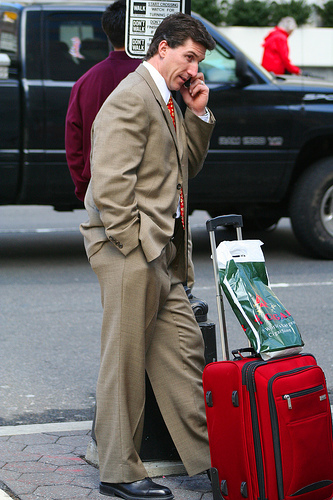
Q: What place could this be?
A: It is a street.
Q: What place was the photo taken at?
A: It was taken at the street.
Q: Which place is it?
A: It is a street.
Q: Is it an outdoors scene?
A: Yes, it is outdoors.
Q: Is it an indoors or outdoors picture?
A: It is outdoors.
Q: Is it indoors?
A: No, it is outdoors.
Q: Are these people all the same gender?
A: No, they are both male and female.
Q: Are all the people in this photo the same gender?
A: No, they are both male and female.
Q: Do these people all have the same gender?
A: No, they are both male and female.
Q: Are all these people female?
A: No, they are both male and female.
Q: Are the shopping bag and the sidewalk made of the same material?
A: No, the shopping bag is made of plastic and the sidewalk is made of cement.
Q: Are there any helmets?
A: No, there are no helmets.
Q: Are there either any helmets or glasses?
A: No, there are no helmets or glasses.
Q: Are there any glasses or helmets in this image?
A: No, there are no helmets or glasses.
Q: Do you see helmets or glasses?
A: No, there are no helmets or glasses.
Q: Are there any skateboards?
A: No, there are no skateboards.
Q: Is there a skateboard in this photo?
A: No, there are no skateboards.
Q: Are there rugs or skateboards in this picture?
A: No, there are no skateboards or rugs.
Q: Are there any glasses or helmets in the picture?
A: No, there are no glasses or helmets.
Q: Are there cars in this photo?
A: No, there are no cars.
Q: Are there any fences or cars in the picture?
A: No, there are no cars or fences.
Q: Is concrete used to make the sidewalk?
A: Yes, the sidewalk is made of concrete.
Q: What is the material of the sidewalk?
A: The sidewalk is made of cement.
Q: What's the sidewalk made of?
A: The sidewalk is made of concrete.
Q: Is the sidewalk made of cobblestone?
A: No, the sidewalk is made of concrete.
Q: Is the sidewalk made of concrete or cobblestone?
A: The sidewalk is made of concrete.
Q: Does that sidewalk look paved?
A: Yes, the sidewalk is paved.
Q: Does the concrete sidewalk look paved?
A: Yes, the sidewalk is paved.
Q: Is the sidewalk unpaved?
A: No, the sidewalk is paved.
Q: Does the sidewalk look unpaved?
A: No, the sidewalk is paved.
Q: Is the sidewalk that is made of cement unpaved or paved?
A: The sidewalk is paved.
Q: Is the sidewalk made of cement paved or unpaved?
A: The sidewalk is paved.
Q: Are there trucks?
A: Yes, there is a truck.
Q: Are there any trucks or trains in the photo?
A: Yes, there is a truck.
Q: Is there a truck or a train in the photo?
A: Yes, there is a truck.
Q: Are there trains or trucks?
A: Yes, there is a truck.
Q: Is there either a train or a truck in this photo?
A: Yes, there is a truck.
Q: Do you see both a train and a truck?
A: No, there is a truck but no trains.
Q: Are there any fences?
A: No, there are no fences.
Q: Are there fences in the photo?
A: No, there are no fences.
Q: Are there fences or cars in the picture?
A: No, there are no fences or cars.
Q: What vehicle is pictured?
A: The vehicle is a truck.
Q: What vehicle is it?
A: The vehicle is a truck.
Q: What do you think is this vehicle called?
A: This is a truck.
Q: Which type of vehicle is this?
A: This is a truck.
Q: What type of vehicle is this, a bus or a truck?
A: This is a truck.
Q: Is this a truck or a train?
A: This is a truck.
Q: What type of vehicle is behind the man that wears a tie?
A: The vehicle is a truck.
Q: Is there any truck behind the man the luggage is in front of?
A: Yes, there is a truck behind the man.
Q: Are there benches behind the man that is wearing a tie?
A: No, there is a truck behind the man.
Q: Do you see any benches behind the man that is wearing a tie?
A: No, there is a truck behind the man.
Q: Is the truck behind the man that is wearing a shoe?
A: Yes, the truck is behind the man.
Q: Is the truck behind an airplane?
A: No, the truck is behind the man.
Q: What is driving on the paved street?
A: The truck is driving on the street.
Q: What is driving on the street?
A: The truck is driving on the street.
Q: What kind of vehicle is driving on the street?
A: The vehicle is a truck.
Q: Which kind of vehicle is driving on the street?
A: The vehicle is a truck.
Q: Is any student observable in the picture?
A: No, there are no students.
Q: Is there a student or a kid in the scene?
A: No, there are no students or children.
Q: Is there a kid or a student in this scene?
A: No, there are no students or children.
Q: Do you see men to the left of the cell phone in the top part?
A: Yes, there is a man to the left of the cellphone.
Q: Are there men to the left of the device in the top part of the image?
A: Yes, there is a man to the left of the cellphone.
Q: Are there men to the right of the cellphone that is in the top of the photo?
A: No, the man is to the left of the cell phone.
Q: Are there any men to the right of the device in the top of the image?
A: No, the man is to the left of the cell phone.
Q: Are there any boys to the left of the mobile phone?
A: No, there is a man to the left of the mobile phone.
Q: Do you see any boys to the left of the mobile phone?
A: No, there is a man to the left of the mobile phone.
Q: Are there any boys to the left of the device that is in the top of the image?
A: No, there is a man to the left of the mobile phone.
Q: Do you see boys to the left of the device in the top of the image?
A: No, there is a man to the left of the mobile phone.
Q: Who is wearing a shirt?
A: The man is wearing a shirt.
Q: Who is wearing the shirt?
A: The man is wearing a shirt.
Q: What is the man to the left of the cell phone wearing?
A: The man is wearing a shirt.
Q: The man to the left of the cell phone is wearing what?
A: The man is wearing a shirt.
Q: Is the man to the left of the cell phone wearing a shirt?
A: Yes, the man is wearing a shirt.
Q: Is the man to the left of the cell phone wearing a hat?
A: No, the man is wearing a shirt.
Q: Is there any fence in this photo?
A: No, there are no fences.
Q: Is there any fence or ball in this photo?
A: No, there are no fences or balls.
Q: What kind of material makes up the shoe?
A: The shoe is made of leather.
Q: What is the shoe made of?
A: The shoe is made of leather.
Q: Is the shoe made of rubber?
A: No, the shoe is made of leather.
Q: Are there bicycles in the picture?
A: No, there are no bicycles.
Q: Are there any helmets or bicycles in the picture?
A: No, there are no bicycles or helmets.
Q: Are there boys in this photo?
A: No, there are no boys.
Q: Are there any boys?
A: No, there are no boys.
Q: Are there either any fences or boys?
A: No, there are no boys or fences.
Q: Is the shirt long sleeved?
A: Yes, the shirt is long sleeved.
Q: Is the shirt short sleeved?
A: No, the shirt is long sleeved.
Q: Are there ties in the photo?
A: Yes, there is a tie.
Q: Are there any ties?
A: Yes, there is a tie.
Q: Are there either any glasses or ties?
A: Yes, there is a tie.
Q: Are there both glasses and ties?
A: No, there is a tie but no glasses.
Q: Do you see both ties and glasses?
A: No, there is a tie but no glasses.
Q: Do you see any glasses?
A: No, there are no glasses.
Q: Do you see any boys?
A: No, there are no boys.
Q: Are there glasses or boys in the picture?
A: No, there are no boys or glasses.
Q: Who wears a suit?
A: The man wears a suit.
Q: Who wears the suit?
A: The man wears a suit.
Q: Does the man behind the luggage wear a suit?
A: Yes, the man wears a suit.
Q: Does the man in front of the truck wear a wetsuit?
A: No, the man wears a suit.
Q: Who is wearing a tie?
A: The man is wearing a tie.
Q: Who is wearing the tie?
A: The man is wearing a tie.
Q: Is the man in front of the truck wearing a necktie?
A: Yes, the man is wearing a necktie.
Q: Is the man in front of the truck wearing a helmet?
A: No, the man is wearing a necktie.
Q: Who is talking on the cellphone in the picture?
A: The man is talking on the cellphone.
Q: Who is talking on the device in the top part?
A: The man is talking on the cellphone.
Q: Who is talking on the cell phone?
A: The man is talking on the cellphone.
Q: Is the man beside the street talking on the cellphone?
A: Yes, the man is talking on the cellphone.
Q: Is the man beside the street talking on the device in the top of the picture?
A: Yes, the man is talking on the cellphone.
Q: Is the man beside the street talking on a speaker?
A: No, the man is talking on the cellphone.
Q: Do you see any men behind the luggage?
A: Yes, there is a man behind the luggage.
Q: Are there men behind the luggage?
A: Yes, there is a man behind the luggage.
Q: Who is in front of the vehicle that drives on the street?
A: The man is in front of the truck.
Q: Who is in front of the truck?
A: The man is in front of the truck.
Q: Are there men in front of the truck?
A: Yes, there is a man in front of the truck.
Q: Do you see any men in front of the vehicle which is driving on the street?
A: Yes, there is a man in front of the truck.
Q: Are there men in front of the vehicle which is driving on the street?
A: Yes, there is a man in front of the truck.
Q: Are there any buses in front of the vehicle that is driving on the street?
A: No, there is a man in front of the truck.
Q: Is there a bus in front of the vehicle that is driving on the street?
A: No, there is a man in front of the truck.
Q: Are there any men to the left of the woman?
A: Yes, there is a man to the left of the woman.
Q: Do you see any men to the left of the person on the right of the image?
A: Yes, there is a man to the left of the woman.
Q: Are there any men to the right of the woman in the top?
A: No, the man is to the left of the woman.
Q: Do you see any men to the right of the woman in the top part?
A: No, the man is to the left of the woman.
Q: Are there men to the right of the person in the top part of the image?
A: No, the man is to the left of the woman.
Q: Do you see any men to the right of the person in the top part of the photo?
A: No, the man is to the left of the woman.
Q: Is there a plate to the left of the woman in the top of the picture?
A: No, there is a man to the left of the woman.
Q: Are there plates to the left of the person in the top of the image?
A: No, there is a man to the left of the woman.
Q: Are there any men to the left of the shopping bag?
A: Yes, there is a man to the left of the shopping bag.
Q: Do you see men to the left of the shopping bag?
A: Yes, there is a man to the left of the shopping bag.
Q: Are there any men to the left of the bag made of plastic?
A: Yes, there is a man to the left of the shopping bag.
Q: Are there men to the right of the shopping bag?
A: No, the man is to the left of the shopping bag.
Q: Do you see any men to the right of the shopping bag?
A: No, the man is to the left of the shopping bag.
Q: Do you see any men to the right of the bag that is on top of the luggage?
A: No, the man is to the left of the shopping bag.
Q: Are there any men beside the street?
A: Yes, there is a man beside the street.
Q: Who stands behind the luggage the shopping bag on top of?
A: The man stands behind the luggage.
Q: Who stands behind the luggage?
A: The man stands behind the luggage.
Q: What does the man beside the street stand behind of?
A: The man stands behind the luggage.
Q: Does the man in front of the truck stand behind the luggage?
A: Yes, the man stands behind the luggage.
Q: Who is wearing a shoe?
A: The man is wearing a shoe.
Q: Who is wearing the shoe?
A: The man is wearing a shoe.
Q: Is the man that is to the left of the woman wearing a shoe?
A: Yes, the man is wearing a shoe.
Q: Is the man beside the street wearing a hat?
A: No, the man is wearing a shoe.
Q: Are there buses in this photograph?
A: No, there are no buses.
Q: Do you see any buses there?
A: No, there are no buses.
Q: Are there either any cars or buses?
A: No, there are no buses or cars.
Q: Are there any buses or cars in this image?
A: No, there are no buses or cars.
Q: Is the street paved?
A: Yes, the street is paved.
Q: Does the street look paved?
A: Yes, the street is paved.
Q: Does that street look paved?
A: Yes, the street is paved.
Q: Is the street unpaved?
A: No, the street is paved.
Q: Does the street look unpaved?
A: No, the street is paved.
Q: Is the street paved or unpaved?
A: The street is paved.